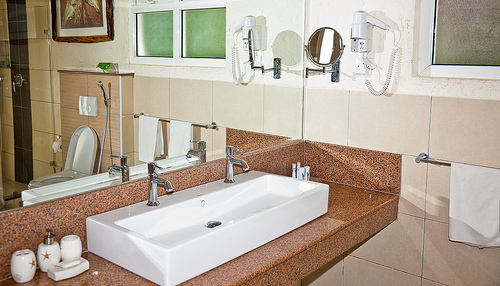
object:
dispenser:
[36, 228, 61, 273]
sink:
[85, 171, 330, 286]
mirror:
[306, 27, 342, 66]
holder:
[8, 248, 35, 284]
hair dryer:
[349, 10, 400, 98]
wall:
[304, 0, 499, 286]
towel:
[447, 163, 500, 250]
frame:
[50, 0, 115, 44]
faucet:
[225, 145, 250, 183]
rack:
[413, 153, 449, 168]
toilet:
[28, 125, 99, 189]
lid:
[63, 125, 99, 176]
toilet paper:
[51, 141, 62, 153]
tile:
[302, 89, 347, 145]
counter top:
[0, 139, 402, 285]